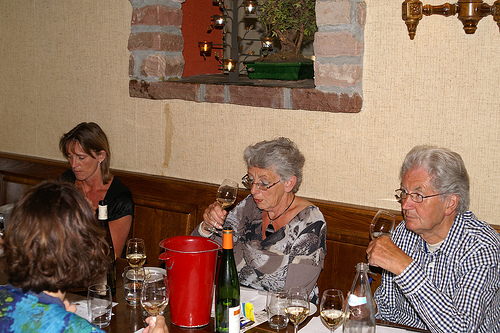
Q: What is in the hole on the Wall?
A: Plant.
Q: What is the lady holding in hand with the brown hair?
A: A wine glass.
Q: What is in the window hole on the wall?
A: Tree.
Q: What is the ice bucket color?
A: Red.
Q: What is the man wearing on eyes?
A: Glasses.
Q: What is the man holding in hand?
A: Wine glass.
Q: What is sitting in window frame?
A: Plant.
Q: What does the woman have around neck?
A: Necklace.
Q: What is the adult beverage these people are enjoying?
A: Wine.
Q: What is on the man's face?
A: Glasses.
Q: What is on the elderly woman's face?
A: Glasses.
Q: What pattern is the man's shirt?
A: Checkered.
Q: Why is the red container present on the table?
A: To chill the wine.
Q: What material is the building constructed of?
A: Brick.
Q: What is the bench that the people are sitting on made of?
A: Wood.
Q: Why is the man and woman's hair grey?
A: They are old.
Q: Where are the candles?
A: Above the woman with gray hair.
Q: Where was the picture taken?
A: Restaurant.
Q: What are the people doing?
A: Drinking.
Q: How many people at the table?
A: Four.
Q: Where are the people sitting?
A: In a restaurant.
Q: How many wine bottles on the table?
A: Two.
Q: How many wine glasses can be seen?
A: Six.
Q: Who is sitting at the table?
A: Three women and a man.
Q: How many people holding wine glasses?
A: Three.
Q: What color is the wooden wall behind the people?
A: Brown.